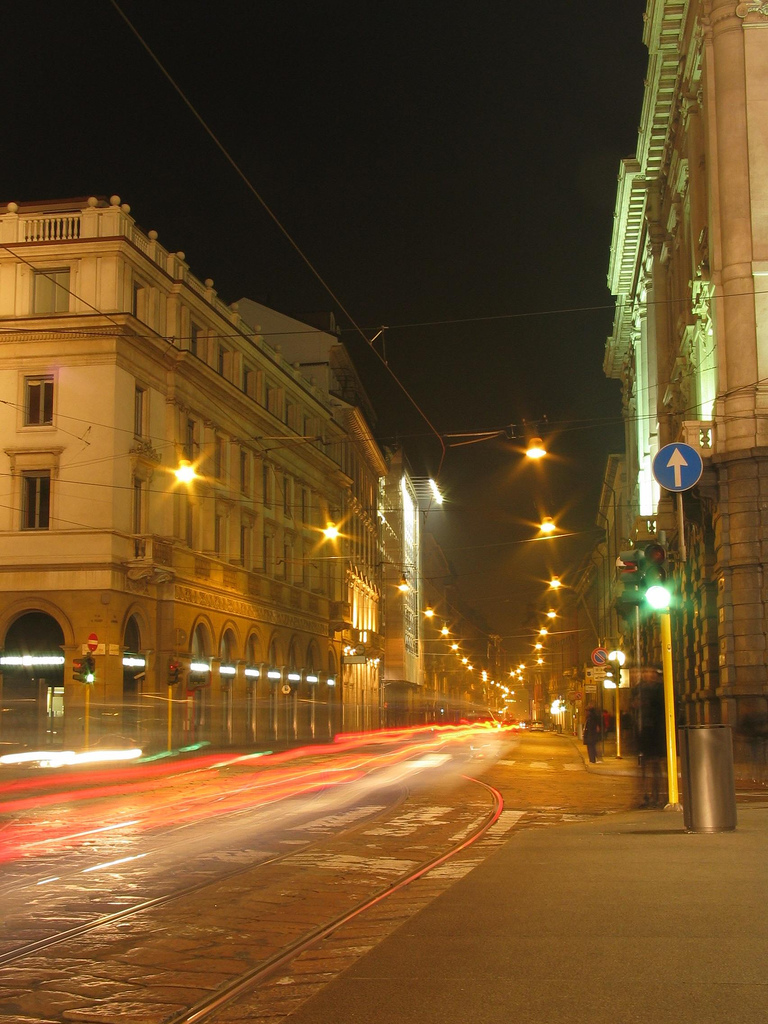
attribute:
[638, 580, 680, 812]
light — green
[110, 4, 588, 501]
wires — overhead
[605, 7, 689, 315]
roof — notched, trim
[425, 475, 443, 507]
lights — white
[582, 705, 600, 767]
woman — standing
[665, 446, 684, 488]
arrow — pointed, upwards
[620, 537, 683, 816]
lamp — street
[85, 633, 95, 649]
sign — Do No Enter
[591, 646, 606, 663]
sign — No Access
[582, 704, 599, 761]
person — waiting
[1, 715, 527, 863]
blur — tail lights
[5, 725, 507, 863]
light — red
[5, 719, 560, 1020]
road — cobblestone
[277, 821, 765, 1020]
sidewalk — dark gray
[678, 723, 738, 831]
trashcan — gray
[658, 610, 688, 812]
pole — bright, yellow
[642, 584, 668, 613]
light — green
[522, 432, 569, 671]
lights — twinkling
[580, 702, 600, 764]
person — walking